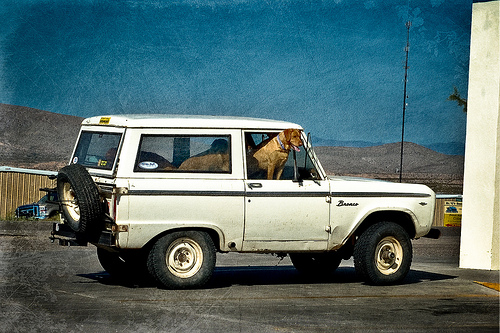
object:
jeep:
[37, 109, 441, 293]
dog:
[246, 124, 308, 181]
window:
[239, 130, 323, 182]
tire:
[145, 224, 224, 292]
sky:
[1, 1, 472, 154]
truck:
[12, 181, 61, 221]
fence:
[0, 166, 58, 220]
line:
[121, 290, 492, 304]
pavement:
[1, 229, 496, 333]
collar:
[273, 134, 291, 153]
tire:
[348, 212, 418, 286]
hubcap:
[164, 237, 203, 279]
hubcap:
[372, 237, 405, 276]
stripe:
[121, 189, 434, 201]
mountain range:
[0, 99, 464, 195]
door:
[241, 179, 333, 245]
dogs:
[178, 137, 232, 172]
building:
[449, 0, 499, 276]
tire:
[45, 161, 104, 243]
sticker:
[97, 117, 113, 127]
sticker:
[97, 159, 109, 168]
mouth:
[291, 143, 304, 152]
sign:
[441, 197, 463, 217]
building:
[429, 188, 462, 229]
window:
[132, 130, 233, 175]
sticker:
[137, 160, 159, 171]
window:
[67, 123, 123, 174]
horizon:
[1, 1, 464, 183]